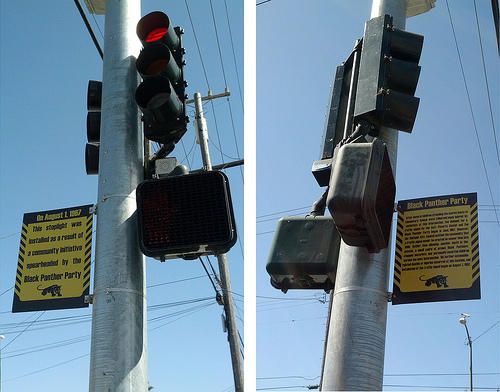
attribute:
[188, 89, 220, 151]
transformer — electrical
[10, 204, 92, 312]
sign — yellow, black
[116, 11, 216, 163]
light — street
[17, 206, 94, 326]
sign — yellow, black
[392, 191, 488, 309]
sign — black, yellow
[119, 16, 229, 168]
light — red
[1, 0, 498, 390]
sky — clear, blue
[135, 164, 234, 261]
light — off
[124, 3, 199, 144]
light — street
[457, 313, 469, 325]
light — white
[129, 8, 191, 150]
light — red, on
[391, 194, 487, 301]
sign — black panther party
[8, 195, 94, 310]
sign — black panther party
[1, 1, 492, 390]
blue sky — cloudless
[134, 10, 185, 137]
traffic light — black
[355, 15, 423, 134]
traffic light — black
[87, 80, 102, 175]
traffic light — black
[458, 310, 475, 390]
street lamp — off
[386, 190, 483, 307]
sign — black, yellow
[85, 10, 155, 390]
pole — steel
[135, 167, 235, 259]
signal — pedistrian traffic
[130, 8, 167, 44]
light — black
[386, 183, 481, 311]
sign — black panther party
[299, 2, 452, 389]
pole — metal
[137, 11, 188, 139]
light — off, black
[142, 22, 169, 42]
light — red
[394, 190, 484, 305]
sign — yellow, black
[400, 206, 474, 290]
background — yellow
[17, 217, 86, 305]
background — yellow